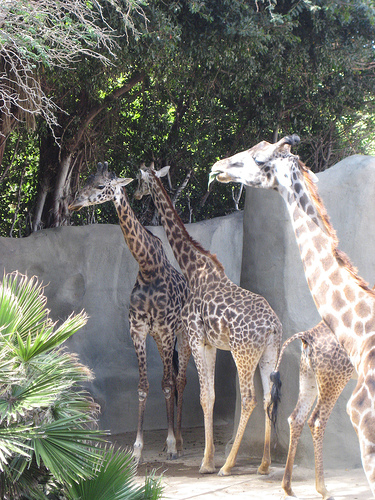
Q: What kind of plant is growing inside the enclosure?
A: Small palm tree.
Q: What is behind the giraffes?
A: Cement wall.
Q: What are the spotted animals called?
A: Giraffes.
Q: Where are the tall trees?
A: Behind the wall.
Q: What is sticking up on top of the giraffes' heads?
A: Horns.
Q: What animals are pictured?
A: Giraffes.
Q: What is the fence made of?
A: Cement.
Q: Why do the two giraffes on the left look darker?
A: Standing in the shade.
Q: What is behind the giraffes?
A: Cement wall.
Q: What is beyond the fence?
A: Trees.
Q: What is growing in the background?
A: Grove of trees.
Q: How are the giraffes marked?
A: Brown spots on yellow background.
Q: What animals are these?
A: Giraffes.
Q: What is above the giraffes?
A: A tree.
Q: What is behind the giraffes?
A: A wall.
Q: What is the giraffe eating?
A: A leaf.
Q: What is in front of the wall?
A: Three giraffes.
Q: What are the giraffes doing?
A: Eating.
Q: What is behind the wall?
A: Trees.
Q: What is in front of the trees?
A: A wall.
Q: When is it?
A: Day time.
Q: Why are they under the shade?
A: To rest.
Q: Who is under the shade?
A: The giraffe.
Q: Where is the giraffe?
A: Under the shade.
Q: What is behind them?
A: The wall.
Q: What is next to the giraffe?
A: Tree.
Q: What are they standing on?
A: The ground.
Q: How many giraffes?
A: 3.